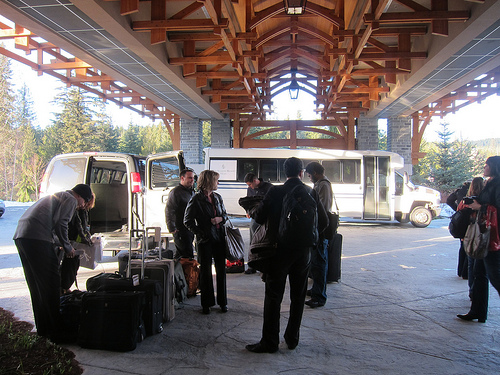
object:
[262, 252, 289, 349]
trouser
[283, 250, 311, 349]
trouser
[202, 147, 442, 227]
ride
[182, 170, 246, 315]
person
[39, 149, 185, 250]
ride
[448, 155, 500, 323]
person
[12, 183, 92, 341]
person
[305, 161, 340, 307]
person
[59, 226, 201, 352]
luggages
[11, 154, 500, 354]
people waiting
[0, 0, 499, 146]
structure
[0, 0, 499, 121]
overhead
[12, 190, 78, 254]
shirt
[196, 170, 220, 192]
turned head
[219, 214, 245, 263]
purse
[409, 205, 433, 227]
front tire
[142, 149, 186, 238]
door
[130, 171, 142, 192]
tail-light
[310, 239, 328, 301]
part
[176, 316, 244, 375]
ground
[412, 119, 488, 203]
bush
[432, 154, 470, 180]
leaves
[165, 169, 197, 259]
person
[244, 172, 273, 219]
person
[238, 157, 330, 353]
group of people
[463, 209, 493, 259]
bag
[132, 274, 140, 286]
tag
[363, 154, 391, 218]
large doors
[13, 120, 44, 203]
tree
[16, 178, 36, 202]
green leaves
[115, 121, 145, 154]
tree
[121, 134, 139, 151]
green leaves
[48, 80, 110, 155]
tree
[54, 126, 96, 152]
green leaves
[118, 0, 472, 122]
ceiling rafters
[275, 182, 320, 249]
backpack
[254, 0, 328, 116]
ceiling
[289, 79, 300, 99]
light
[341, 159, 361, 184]
window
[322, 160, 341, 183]
window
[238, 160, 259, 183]
window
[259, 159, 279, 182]
window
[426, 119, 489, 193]
tree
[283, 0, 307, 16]
light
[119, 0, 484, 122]
beams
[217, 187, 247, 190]
blue stripe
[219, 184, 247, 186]
blue stripe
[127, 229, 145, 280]
handle of suitcase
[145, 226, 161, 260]
handle of suitcase